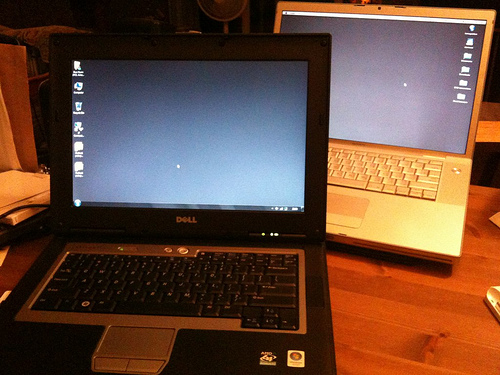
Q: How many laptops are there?
A: Two.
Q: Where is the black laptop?
A: In front of the silver one.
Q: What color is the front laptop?
A: Black.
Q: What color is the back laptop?
A: Silver.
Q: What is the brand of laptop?
A: Dell.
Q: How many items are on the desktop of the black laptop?
A: Six.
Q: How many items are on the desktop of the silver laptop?
A: Six.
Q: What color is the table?
A: Brown.